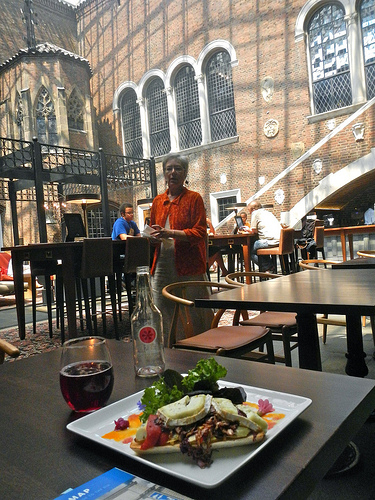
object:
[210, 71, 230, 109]
mesh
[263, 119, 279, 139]
cement brick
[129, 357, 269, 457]
sandwich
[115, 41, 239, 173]
windows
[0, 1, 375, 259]
building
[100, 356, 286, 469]
food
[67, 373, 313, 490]
plate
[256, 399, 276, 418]
flower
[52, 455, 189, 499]
paper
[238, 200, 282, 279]
man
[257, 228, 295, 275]
chair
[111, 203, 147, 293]
man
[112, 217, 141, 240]
shirt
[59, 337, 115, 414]
glass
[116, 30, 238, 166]
man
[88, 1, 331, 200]
wall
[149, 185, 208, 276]
shirt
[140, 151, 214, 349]
person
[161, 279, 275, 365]
chair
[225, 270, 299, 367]
chair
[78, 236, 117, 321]
chair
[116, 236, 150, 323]
chair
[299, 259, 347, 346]
chair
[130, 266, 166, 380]
bottle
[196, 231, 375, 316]
table